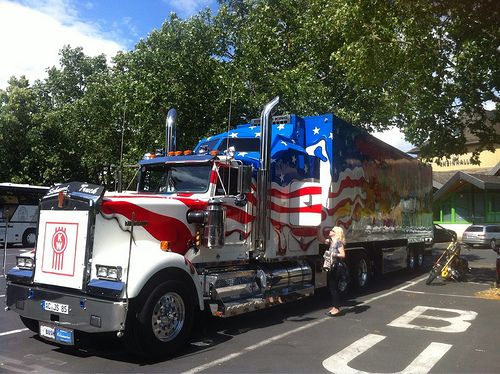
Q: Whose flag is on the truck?
A: United States'.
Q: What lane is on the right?
A: Bus Lane.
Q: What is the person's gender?
A: Female.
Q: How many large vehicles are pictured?
A: Two.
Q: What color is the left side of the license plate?
A: Blue.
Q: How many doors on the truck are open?
A: One.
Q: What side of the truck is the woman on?
A: Drivers' side.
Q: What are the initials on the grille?
A: KW.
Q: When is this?
A: Daytime.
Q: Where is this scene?
A: A parking lot.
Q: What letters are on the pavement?
A: BU.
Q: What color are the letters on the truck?
A: White.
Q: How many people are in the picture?
A: One.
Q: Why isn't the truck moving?
A: It is parked.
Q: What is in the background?
A: Trees.